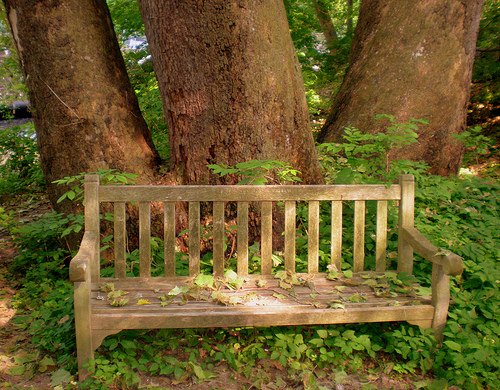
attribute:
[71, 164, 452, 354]
bench — vacant, brown, wooden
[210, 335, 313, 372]
plant — green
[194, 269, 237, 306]
leaves — scattered, green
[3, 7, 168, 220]
tree — here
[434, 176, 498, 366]
foliage — green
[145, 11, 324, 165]
trunk — brown, large, thick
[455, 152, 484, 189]
sun — shining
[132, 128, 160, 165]
bark — missing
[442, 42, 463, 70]
moss — growning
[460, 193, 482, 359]
ivy — growing